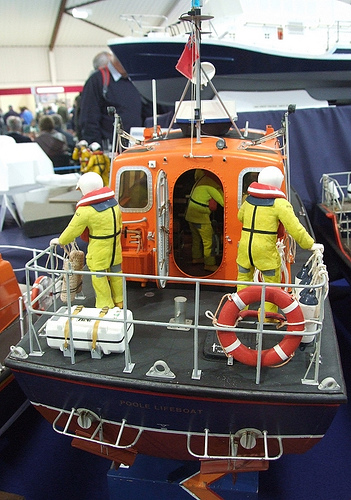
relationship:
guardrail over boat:
[23, 261, 337, 388] [2, 31, 348, 448]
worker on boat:
[230, 171, 325, 314] [2, 31, 348, 448]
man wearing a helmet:
[51, 172, 138, 311] [76, 172, 104, 197]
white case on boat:
[45, 295, 137, 350] [2, 31, 348, 448]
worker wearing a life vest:
[230, 171, 325, 314] [242, 182, 281, 203]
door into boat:
[167, 164, 232, 282] [2, 31, 348, 448]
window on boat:
[111, 166, 153, 215] [2, 31, 348, 448]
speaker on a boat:
[189, 55, 218, 91] [2, 31, 348, 448]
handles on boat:
[145, 226, 153, 250] [2, 31, 348, 448]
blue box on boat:
[171, 92, 237, 136] [2, 31, 348, 448]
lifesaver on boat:
[207, 282, 310, 372] [2, 31, 348, 448]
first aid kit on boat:
[45, 295, 137, 350] [2, 31, 348, 448]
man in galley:
[190, 184, 215, 256] [173, 176, 216, 277]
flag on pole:
[177, 31, 196, 85] [194, 36, 205, 138]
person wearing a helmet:
[51, 172, 138, 311] [74, 172, 107, 202]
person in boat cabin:
[190, 184, 215, 256] [173, 176, 216, 277]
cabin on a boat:
[108, 130, 285, 277] [2, 31, 348, 448]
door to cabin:
[167, 164, 232, 282] [108, 130, 285, 277]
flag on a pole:
[177, 31, 196, 85] [194, 36, 205, 138]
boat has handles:
[2, 31, 348, 448] [145, 226, 153, 250]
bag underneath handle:
[299, 287, 319, 346] [311, 269, 330, 286]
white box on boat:
[45, 295, 137, 350] [2, 31, 348, 448]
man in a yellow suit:
[51, 172, 138, 311] [67, 202, 144, 309]